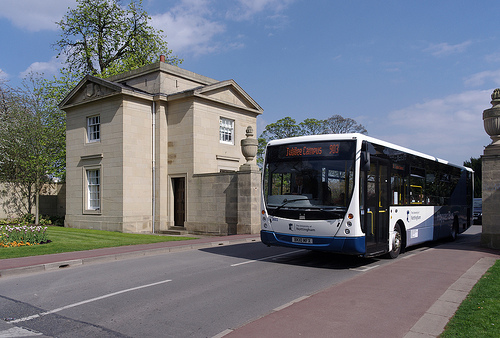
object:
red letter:
[284, 143, 340, 156]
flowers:
[22, 225, 27, 228]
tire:
[387, 229, 407, 258]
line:
[0, 276, 175, 328]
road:
[2, 214, 482, 335]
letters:
[328, 143, 341, 154]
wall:
[184, 162, 262, 239]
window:
[80, 112, 104, 143]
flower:
[19, 227, 22, 229]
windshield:
[258, 138, 364, 211]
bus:
[257, 133, 477, 261]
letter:
[285, 147, 289, 156]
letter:
[302, 147, 315, 156]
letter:
[318, 146, 323, 154]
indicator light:
[347, 213, 354, 219]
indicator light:
[345, 221, 352, 228]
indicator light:
[343, 228, 351, 235]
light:
[283, 143, 343, 157]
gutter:
[148, 105, 170, 237]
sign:
[265, 135, 362, 158]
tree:
[48, 3, 171, 95]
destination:
[283, 144, 340, 157]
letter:
[285, 147, 302, 157]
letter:
[302, 146, 306, 156]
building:
[59, 54, 263, 237]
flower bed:
[0, 221, 48, 246]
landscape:
[3, 226, 143, 263]